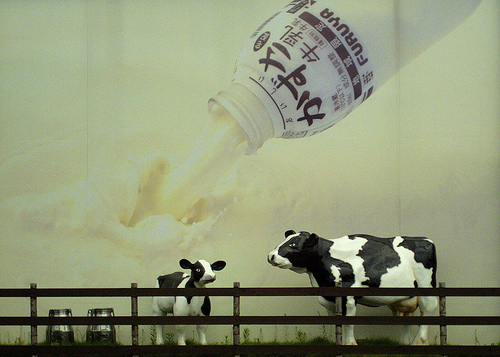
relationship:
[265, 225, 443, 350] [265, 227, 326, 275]
cow has head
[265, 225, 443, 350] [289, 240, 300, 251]
cow has eye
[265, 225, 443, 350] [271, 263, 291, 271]
cow has mouth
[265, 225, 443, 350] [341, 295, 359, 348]
cow has leg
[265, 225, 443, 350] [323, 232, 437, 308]
cow has body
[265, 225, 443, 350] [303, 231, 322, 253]
cow has ear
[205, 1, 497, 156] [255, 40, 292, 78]
bottle has character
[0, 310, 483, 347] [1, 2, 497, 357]
grass painted on billboard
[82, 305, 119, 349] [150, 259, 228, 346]
tub next to cow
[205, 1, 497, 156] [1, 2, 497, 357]
bottle on face of billboard